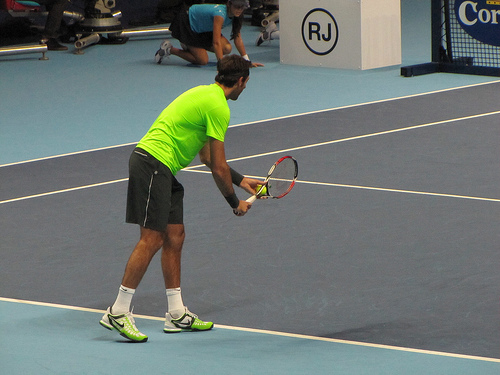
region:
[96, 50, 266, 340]
Male tennis player preparing to serve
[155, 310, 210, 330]
Green and white shoe on tennis player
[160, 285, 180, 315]
White sock on tennis player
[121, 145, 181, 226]
Black shorts on tennis player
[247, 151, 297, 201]
Red, white, and blue tennis racket held by player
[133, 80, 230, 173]
Green shirt on tennis player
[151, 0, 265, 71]
Ball girl in crouch at tennis match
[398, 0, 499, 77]
Part of net at tennis court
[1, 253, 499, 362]
White baseline on tennis court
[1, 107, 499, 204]
White sideline on tennis court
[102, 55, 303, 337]
A tennis player preparing to serve the ball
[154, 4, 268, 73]
A woman waiting to retrieve lost balls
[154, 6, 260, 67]
A woman in a blue T-shirt, black skirt, and a cap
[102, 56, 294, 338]
A man in bright yellow-green shirt and shoes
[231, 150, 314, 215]
A white, black, and red tennis racket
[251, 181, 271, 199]
A tennis ball in the man's left hand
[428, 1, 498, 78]
A tennis net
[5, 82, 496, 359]
A competition tennis court with a player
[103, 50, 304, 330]
A competitive male tennis player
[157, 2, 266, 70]
A woman kneeling on the ground to the side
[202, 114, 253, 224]
the hand of a person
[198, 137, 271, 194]
the hand of a person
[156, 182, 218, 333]
the leg of a person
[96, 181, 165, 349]
the leg of a person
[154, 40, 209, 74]
the leg of a person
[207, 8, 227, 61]
the hand of a person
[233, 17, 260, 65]
the hand of a person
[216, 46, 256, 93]
the head of a person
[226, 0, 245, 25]
the head of a person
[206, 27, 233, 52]
the leg of a person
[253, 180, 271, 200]
Green tennis ball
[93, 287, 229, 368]
Green,white an black tennis shoes.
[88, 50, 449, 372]
A tennis court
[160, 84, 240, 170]
The man's shirt is bright green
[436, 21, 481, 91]
A tennis court net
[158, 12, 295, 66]
A woman kneeling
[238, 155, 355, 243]
A white, red and black tennis racket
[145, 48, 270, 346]
Tennis is getting ready to serve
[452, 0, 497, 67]
black net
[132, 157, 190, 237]
A pair of shorts with white lining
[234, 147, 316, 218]
a tennis racket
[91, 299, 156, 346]
a green and white shoe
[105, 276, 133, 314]
a white sock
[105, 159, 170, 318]
the leg of a man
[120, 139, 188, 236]
a black pair of shorts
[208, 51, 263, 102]
the head of a man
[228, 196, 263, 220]
the hand of a man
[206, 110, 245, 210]
the arm of a man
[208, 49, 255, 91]
the black hair of a man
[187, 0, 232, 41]
a blue tee shirt